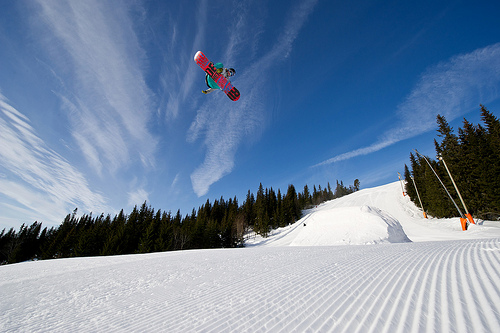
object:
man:
[201, 62, 237, 94]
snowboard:
[193, 50, 241, 101]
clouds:
[0, 0, 499, 237]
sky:
[0, 0, 500, 237]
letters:
[210, 71, 221, 83]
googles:
[229, 69, 233, 76]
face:
[227, 67, 236, 77]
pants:
[202, 62, 224, 94]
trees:
[0, 178, 369, 265]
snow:
[0, 182, 499, 332]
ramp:
[252, 179, 500, 249]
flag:
[396, 171, 401, 180]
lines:
[193, 237, 500, 333]